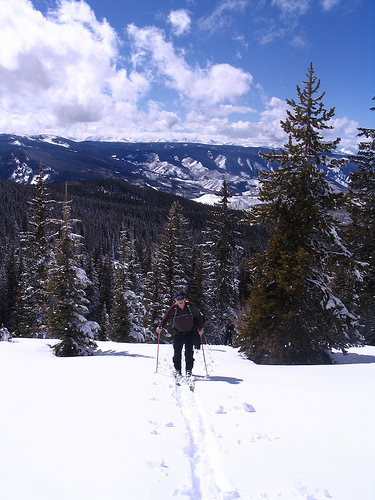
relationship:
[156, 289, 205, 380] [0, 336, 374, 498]
man on hill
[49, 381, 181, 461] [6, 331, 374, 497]
snow on ground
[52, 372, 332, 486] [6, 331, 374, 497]
snow on ground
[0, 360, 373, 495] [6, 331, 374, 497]
snow on ground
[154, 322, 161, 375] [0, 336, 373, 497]
ski poles in snow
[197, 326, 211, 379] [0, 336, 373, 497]
ski poles in snow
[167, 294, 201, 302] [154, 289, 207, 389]
hat on skier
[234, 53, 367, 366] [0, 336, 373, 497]
tall tree in snow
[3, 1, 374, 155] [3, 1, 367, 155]
clouds in sky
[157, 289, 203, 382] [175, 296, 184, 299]
man in shade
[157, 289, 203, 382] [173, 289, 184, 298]
man in hat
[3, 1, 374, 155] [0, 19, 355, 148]
clouds in sky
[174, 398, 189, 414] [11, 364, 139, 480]
track in snow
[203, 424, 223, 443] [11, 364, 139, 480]
track in snow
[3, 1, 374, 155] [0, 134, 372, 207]
clouds on mountains